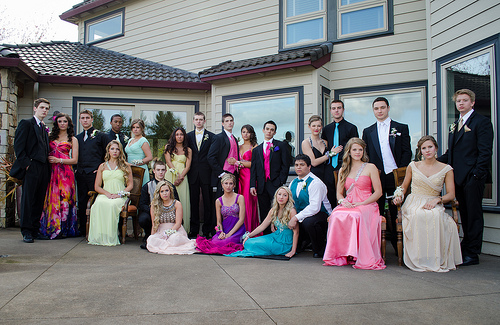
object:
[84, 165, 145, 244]
chair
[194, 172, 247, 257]
girl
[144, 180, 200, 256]
girl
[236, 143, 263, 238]
dress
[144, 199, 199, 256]
dress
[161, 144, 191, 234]
dress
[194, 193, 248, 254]
dress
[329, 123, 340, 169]
blue tie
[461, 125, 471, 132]
pocket square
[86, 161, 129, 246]
dress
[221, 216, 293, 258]
dress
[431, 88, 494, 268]
boy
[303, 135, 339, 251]
dress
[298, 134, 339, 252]
gown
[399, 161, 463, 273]
gown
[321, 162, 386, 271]
gown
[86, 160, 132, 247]
gown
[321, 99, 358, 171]
man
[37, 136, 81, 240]
dress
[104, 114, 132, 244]
black man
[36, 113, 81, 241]
girl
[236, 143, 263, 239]
gown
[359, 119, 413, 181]
tuxedo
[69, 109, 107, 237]
man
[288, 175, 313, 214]
blue vest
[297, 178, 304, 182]
blue tie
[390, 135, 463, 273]
girl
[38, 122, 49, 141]
tie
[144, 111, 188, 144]
plant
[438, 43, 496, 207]
window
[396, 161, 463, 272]
dress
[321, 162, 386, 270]
dress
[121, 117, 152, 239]
girl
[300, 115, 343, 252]
girl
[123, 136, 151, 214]
dress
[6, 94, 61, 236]
man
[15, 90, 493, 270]
group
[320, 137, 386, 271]
girl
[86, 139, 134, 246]
girl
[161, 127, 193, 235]
girl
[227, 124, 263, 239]
girl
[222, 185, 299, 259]
girl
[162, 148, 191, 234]
gown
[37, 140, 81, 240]
gown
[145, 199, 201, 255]
gown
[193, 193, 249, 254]
gown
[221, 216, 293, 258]
gown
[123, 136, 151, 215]
gown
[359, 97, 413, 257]
man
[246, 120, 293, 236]
man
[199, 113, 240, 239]
man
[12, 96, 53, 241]
man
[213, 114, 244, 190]
man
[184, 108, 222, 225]
man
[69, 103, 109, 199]
man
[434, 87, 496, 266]
man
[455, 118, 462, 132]
tie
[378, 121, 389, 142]
tie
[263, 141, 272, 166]
tie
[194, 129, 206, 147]
tie